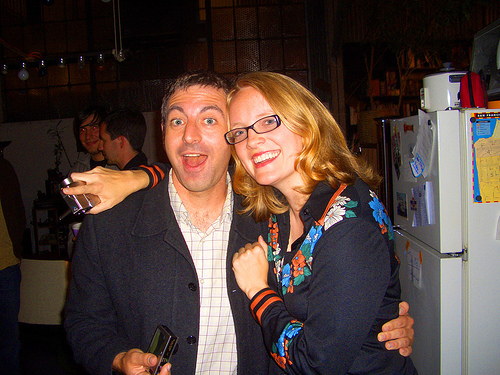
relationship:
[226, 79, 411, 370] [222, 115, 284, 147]
woman wearing glasses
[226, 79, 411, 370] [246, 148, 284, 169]
woman with smile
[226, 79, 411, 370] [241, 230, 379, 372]
woman has hand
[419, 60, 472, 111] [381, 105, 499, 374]
crock pot on fridge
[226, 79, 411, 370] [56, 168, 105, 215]
woman holding camera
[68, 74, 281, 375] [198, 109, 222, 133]
man has left eye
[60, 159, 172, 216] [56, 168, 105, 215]
hand holding camera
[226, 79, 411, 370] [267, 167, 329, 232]
woman has neck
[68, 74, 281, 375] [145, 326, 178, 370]
man holding camera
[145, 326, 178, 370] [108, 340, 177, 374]
camera in hand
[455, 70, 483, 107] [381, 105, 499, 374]
bag on top of fridge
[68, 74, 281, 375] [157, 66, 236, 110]
man has hair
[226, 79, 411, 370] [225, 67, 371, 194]
woman has hair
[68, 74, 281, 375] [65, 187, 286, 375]
man wearing jacket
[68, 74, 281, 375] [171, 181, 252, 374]
man wearing shirt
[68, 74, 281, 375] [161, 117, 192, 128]
man has eye brows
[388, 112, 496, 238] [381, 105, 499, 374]
papers on fridge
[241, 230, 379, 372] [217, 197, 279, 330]
hand on man's chest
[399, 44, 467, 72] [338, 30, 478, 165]
books on shelf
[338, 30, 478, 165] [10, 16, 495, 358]
shelf in background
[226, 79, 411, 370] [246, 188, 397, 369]
woman wears shirt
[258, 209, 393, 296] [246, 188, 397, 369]
flowers on shirt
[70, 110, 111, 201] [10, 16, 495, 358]
person in background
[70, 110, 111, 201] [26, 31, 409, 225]
person looking at camera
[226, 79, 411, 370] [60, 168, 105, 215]
woman holding camera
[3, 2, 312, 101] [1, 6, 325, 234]
tiles on wall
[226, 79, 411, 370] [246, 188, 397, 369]
woman wearing shirt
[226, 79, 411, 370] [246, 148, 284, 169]
woman has maxillary dentition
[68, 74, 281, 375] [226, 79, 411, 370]
man holding woman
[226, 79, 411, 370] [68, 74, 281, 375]
woman holding man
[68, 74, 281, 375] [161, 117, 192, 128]
man with eye brows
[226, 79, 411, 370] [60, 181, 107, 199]
woman has pointer finger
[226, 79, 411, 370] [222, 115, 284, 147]
woman wears glasses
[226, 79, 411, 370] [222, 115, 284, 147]
woman wear glasses